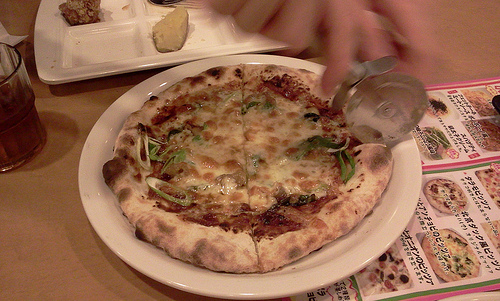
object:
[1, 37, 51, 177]
glass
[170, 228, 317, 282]
crust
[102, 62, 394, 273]
pizza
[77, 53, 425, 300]
plate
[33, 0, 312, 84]
tray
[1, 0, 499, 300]
table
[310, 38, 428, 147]
pizza cutter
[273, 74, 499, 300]
menu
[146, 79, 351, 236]
cheese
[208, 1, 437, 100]
hand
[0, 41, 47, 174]
cup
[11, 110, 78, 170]
shadow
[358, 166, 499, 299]
selections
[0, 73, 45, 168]
liquid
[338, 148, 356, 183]
vegetable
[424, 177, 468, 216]
pizza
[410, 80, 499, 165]
pictures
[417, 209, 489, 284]
pictures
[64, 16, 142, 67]
squares